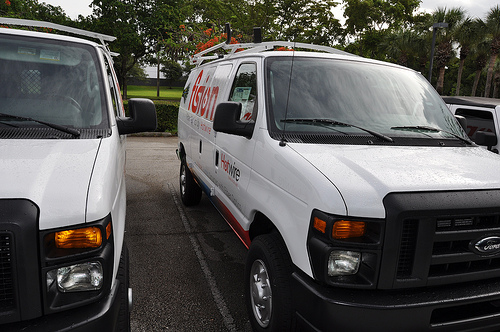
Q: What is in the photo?
A: Vans.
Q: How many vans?
A: 2.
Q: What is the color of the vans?
A: White.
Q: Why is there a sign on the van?
A: For business.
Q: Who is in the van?
A: Nobody.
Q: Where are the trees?
A: Behind the vans.